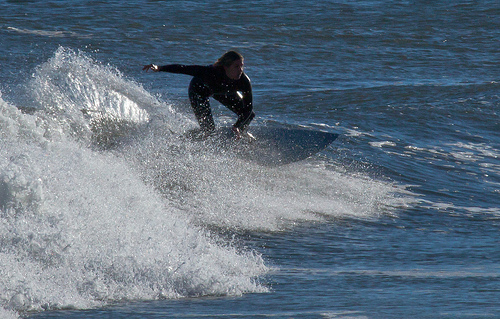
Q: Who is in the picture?
A: A man.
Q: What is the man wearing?
A: A wetsuit.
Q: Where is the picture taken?
A: The ocean.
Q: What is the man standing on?
A: A surfboard.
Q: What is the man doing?
A: Surfing.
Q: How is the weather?
A: Sunny.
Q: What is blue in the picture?
A: Water.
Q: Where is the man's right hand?
A: The air.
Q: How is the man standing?
A: Crouching.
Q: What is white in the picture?
A: The wave's crest.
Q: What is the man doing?
A: Surfing.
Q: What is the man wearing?
A: Wetsuit.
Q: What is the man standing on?
A: Surfboard.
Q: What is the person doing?
A: Surfing.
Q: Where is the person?
A: In the ocean.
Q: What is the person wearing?
A: Wetsuit.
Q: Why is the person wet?
A: In the water.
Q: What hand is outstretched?
A: The right.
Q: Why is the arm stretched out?
A: For balance.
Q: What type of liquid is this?
A: Water.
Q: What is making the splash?
A: Wave.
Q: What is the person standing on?
A: Surfboard.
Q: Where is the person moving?
A: Toward the shore.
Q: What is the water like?
A: Roaring.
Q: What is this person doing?
A: Surfing.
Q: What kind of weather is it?
A: Sunny.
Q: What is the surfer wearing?
A: Wet suit.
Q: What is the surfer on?
A: Surfboard.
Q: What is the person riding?
A: A wave.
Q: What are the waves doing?
A: Crashing.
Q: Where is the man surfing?
A: Ocean.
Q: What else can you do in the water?
A: Swim.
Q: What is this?
A: Surfing.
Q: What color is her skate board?
A: Blue.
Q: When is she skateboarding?
A: During the day.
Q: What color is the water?
A: Blue.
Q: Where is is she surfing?
A: In the ocean.